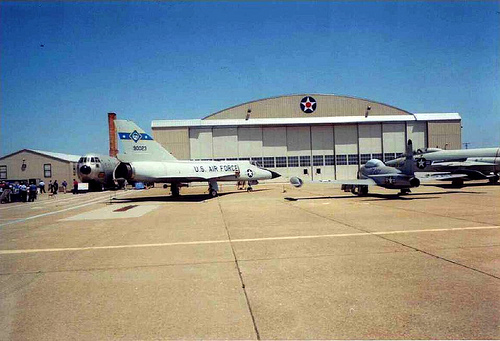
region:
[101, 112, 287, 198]
a white plane on the ground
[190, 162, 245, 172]
writing on the plane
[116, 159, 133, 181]
the afterburner on the plane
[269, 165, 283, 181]
the nose of the plane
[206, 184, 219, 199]
a wheel of the plane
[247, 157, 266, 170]
the cockpit of the plane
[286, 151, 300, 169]
a window on the building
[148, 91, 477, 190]
a plane hanger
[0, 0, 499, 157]
a clear blue sky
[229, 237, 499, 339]
a slab of cement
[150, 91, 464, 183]
a large aircraft hangar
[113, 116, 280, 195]
a U.S. fighter jet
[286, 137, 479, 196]
a small jet plane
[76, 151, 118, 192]
the nose of a large plane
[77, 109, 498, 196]
a group of planes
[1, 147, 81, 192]
a small tan building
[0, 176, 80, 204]
a group of people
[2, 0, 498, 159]
an empty blue sky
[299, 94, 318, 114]
a blue, white and red logo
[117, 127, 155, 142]
a blue stripe on the planes tail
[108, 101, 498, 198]
Planes parked in an airport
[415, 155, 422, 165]
Star sign on the plane on the right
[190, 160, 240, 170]
Words on the white plane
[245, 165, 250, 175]
Star sign on the white plane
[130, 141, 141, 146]
Numbers on the tail of the white plane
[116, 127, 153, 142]
Picture on the tail of the white plane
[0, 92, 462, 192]
Buildings in the airport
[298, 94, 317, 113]
Star sign on the bigger building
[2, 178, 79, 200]
People standing in front of the smaller building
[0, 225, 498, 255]
White line on the floor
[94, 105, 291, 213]
a white plane in front a building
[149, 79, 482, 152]
a building behind planes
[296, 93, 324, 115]
a logotype on top of building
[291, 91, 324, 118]
logo is a blue circle with a white star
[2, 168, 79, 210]
a group of people in front a building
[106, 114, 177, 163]
vertical stabilizer of plane is large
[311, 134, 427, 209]
small plane color gray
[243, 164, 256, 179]
a logotype on side of plane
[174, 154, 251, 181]
side of plane says "US Air Force"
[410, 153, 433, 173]
logotype on side of plane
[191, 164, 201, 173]
the blue letter u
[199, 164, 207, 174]
the blue letter s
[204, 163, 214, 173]
the blue letter A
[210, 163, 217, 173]
the blue letter I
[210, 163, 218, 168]
the blue letter R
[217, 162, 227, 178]
the blue letter F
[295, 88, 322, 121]
this is a star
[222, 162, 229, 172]
the blue letter O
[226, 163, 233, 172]
the blue letter R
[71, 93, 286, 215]
this is a jet